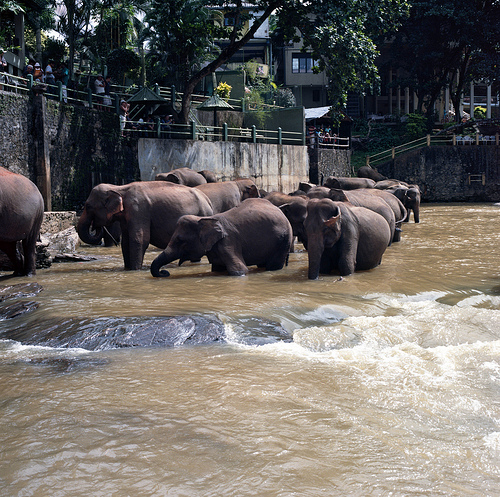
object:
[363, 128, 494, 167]
railing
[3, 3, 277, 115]
green overhang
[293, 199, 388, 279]
elephant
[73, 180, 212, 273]
elephant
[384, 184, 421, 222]
elephant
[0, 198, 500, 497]
water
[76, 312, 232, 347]
rocks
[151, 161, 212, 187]
elephant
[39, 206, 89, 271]
wall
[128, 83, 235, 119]
umbrella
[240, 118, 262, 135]
table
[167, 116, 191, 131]
chairs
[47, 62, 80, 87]
person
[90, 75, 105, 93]
shirt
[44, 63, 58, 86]
people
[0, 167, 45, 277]
elephant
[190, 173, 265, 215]
elephant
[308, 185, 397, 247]
elephant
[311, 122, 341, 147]
person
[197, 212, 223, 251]
ear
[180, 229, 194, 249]
eye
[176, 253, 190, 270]
mouth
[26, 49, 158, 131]
people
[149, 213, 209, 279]
head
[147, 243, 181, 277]
trunk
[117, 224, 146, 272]
leg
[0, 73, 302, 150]
fence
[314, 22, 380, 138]
tree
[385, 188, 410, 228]
tail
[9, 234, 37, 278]
legs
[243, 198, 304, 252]
rear end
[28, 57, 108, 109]
people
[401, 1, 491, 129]
tree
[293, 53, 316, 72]
window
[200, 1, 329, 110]
building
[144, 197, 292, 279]
elephant